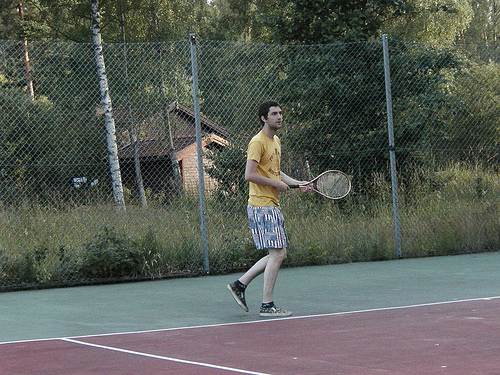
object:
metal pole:
[187, 30, 210, 276]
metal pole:
[382, 33, 404, 260]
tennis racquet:
[288, 169, 353, 201]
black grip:
[288, 184, 299, 189]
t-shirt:
[246, 130, 282, 210]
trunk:
[87, 1, 127, 214]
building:
[29, 98, 247, 205]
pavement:
[0, 249, 497, 374]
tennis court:
[0, 251, 499, 374]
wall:
[173, 132, 237, 200]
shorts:
[245, 203, 290, 250]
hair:
[258, 100, 283, 123]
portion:
[0, 292, 500, 375]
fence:
[0, 0, 499, 291]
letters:
[268, 148, 282, 177]